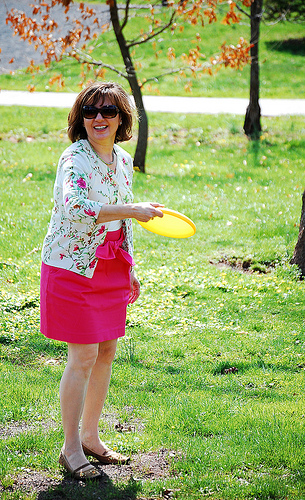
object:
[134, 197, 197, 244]
frisbee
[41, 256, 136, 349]
skirt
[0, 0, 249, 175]
tree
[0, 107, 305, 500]
grass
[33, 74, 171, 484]
lady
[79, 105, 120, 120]
sunglasses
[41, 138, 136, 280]
jacket